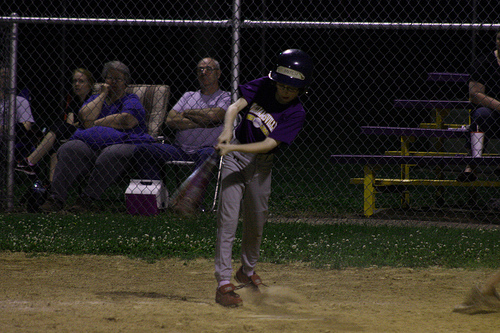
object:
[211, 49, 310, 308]
boy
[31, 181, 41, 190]
ball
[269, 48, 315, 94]
helmet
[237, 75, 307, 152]
shirt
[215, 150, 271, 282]
pants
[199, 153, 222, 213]
bat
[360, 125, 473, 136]
bleachers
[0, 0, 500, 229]
fence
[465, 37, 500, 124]
man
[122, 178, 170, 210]
cooler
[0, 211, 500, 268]
grass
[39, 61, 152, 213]
woman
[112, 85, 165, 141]
chair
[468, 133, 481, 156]
cup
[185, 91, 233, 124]
arms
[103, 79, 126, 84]
glasses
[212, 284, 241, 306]
shoes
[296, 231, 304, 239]
flowers